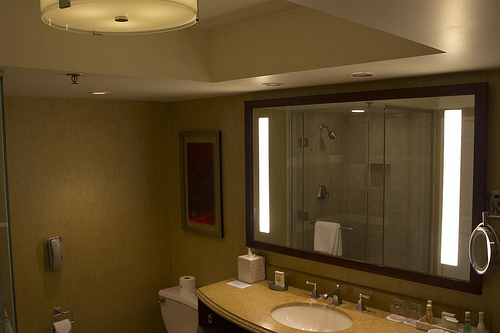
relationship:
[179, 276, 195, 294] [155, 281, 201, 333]
paper on top of toilet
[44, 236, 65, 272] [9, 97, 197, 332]
phone attached to wall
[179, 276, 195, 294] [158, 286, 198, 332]
paper on white toilet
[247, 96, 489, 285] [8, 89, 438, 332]
mirror on wall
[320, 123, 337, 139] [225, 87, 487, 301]
shower in mirror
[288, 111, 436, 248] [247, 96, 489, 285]
shower in mirror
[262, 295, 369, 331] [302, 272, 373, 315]
sink with faucet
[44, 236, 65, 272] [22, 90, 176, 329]
phone on wall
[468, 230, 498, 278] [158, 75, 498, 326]
mirror attached to wall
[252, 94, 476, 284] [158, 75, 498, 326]
mirror attached to wall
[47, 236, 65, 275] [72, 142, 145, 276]
phone on wall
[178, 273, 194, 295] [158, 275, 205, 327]
paper on top of toilet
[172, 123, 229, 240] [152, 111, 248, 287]
painting on wall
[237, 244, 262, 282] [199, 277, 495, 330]
tissue box on counter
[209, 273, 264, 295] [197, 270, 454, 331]
rd on counter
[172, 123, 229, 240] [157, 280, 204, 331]
painting above toilet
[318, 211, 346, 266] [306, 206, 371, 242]
towel on a rack